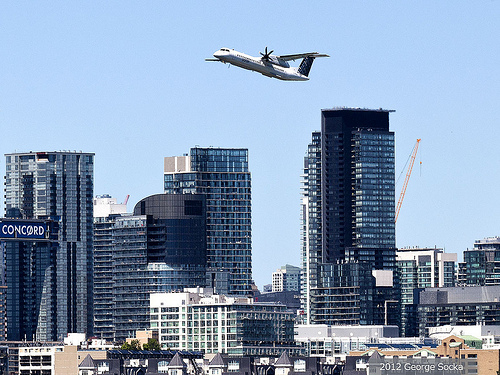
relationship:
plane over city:
[220, 33, 321, 83] [10, 128, 499, 372]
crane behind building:
[395, 143, 429, 214] [350, 127, 408, 237]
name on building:
[11, 214, 59, 235] [0, 156, 91, 335]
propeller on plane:
[252, 47, 274, 69] [220, 33, 321, 83]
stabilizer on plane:
[284, 46, 315, 72] [220, 33, 321, 83]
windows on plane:
[222, 49, 297, 84] [220, 33, 321, 83]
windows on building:
[349, 131, 402, 250] [350, 127, 408, 237]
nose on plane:
[199, 48, 232, 67] [220, 33, 321, 83]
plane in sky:
[220, 33, 321, 83] [37, 14, 161, 79]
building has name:
[0, 156, 91, 335] [11, 214, 59, 235]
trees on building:
[111, 333, 161, 355] [113, 346, 191, 374]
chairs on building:
[198, 285, 240, 303] [157, 290, 299, 347]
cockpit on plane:
[203, 36, 229, 51] [220, 33, 321, 83]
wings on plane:
[247, 41, 322, 69] [220, 33, 321, 83]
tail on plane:
[297, 59, 312, 73] [220, 33, 321, 83]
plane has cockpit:
[220, 33, 321, 83] [203, 36, 229, 51]